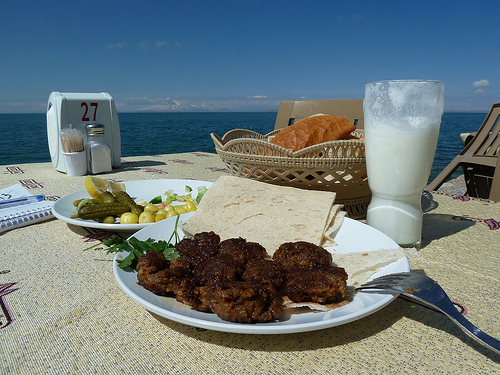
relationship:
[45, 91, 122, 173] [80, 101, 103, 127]
holder with number "27"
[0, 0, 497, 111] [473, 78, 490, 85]
sky with cloud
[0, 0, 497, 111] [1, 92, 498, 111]
sky with cloud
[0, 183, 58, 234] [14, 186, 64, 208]
notebook with pen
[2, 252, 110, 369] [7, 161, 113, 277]
tablecloth on table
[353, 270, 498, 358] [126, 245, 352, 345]
fork on plate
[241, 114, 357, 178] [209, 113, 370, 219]
bread in basket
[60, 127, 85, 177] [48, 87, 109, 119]
toothpicks next to napkins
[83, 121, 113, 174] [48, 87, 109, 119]
salt next to napkins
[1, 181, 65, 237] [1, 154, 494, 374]
notebook on table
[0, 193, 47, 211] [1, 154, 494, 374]
pen on table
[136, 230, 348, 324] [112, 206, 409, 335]
meat on plate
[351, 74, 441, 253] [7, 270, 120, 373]
glass on table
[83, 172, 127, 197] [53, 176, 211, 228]
lemon on plate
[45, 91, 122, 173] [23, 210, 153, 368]
holder on table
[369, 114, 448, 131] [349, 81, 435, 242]
liquid in glass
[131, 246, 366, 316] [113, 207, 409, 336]
food on plate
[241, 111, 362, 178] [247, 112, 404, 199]
bread in basket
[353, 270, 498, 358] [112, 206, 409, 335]
fork on plate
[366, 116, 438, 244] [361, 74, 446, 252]
drink in glass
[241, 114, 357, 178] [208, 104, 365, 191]
bread in basket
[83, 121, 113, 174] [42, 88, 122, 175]
salt in holder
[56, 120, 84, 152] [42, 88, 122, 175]
toothpicks in holder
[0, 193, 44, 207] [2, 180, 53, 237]
pen with notebook